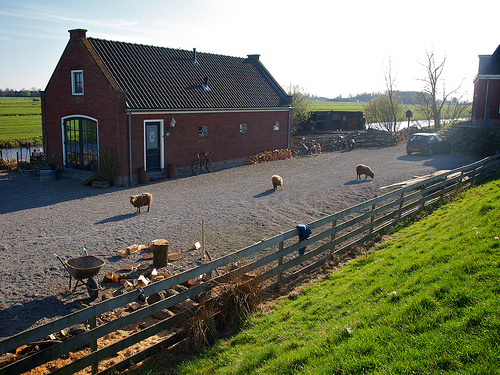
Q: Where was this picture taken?
A: Farm.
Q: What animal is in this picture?
A: Sheep.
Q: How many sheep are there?
A: 3.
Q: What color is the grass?
A: Green.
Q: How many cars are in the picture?
A: 1.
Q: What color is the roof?
A: Black.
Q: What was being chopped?
A: Wood.